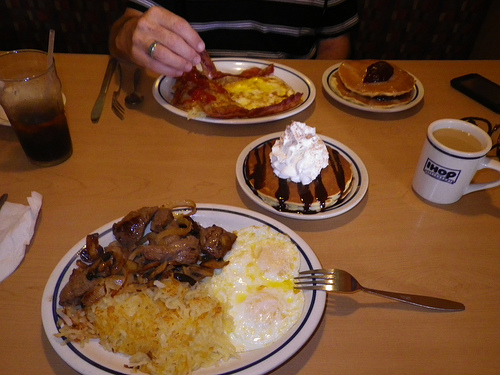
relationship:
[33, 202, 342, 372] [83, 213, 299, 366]
plate of food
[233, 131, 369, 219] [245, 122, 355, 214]
plate of pancake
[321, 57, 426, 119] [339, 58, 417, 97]
plate of pancakes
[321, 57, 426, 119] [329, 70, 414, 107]
plate of pancakes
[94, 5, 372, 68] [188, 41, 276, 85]
person holding bacon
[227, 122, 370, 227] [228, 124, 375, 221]
pancake on plate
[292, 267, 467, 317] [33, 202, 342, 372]
fork on plate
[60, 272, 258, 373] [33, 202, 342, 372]
hash browns on plate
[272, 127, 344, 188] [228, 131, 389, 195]
cream on pancakes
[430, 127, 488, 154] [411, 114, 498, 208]
coffee in cup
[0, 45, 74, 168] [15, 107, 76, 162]
cup with soda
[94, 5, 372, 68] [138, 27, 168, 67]
person wearing ring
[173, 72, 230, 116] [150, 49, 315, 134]
bacon on plate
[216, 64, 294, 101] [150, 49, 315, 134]
eggs on plate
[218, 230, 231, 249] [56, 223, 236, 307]
mushroom on steak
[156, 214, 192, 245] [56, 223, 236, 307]
onion on steak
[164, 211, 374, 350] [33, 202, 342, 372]
eggs on plate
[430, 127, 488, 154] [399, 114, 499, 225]
coffee in cup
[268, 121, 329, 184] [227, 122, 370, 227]
cream on pancake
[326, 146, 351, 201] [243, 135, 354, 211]
chocolate on pancakes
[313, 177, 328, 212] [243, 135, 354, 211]
chocolate on pancakes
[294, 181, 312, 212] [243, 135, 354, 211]
chocolate on pancakes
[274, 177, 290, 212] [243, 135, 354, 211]
chocolate on pancakes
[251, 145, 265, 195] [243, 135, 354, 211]
chocolate on pancakes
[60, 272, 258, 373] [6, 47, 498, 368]
hash browns on table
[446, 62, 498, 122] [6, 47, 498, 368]
cell phone on table